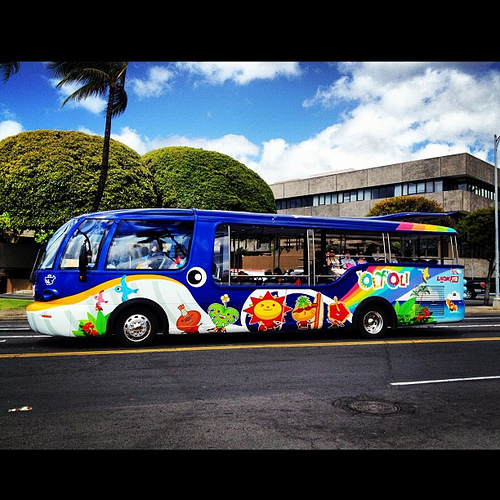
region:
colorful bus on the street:
[36, 210, 466, 336]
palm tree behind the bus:
[56, 56, 116, 205]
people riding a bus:
[231, 265, 294, 285]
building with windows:
[275, 152, 487, 215]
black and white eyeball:
[186, 266, 205, 288]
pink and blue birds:
[91, 277, 137, 304]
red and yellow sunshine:
[245, 290, 287, 332]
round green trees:
[0, 130, 262, 212]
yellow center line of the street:
[0, 340, 487, 360]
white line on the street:
[383, 368, 498, 391]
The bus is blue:
[23, 204, 468, 344]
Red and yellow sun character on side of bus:
[236, 288, 292, 330]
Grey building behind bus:
[273, 147, 493, 299]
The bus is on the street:
[8, 202, 492, 451]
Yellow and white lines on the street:
[0, 307, 497, 434]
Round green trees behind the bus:
[4, 124, 275, 260]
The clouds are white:
[6, 67, 489, 167]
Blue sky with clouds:
[0, 67, 490, 167]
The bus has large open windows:
[205, 211, 456, 298]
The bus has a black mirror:
[72, 232, 92, 288]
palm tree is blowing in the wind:
[55, 59, 127, 207]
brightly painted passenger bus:
[27, 208, 465, 334]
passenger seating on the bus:
[217, 248, 444, 285]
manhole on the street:
[350, 400, 393, 414]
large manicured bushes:
[4, 128, 274, 235]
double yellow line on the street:
[0, 335, 497, 357]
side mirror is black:
[77, 235, 89, 279]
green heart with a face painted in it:
[207, 303, 239, 328]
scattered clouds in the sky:
[5, 63, 498, 181]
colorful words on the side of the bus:
[354, 266, 410, 291]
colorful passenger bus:
[57, 192, 469, 353]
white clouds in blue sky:
[17, 78, 95, 125]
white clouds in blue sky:
[145, 64, 183, 108]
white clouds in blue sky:
[139, 88, 192, 121]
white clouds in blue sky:
[237, 90, 276, 129]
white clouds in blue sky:
[297, 91, 362, 127]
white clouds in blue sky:
[229, 114, 308, 154]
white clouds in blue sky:
[345, 84, 387, 137]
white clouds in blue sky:
[379, 95, 436, 134]